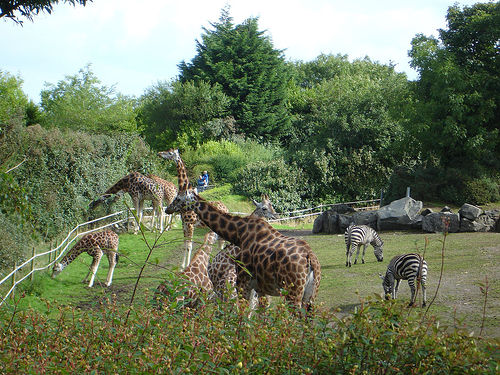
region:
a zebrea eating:
[374, 256, 449, 313]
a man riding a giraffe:
[154, 149, 287, 192]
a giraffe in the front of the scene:
[164, 184, 347, 326]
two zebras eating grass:
[339, 226, 434, 315]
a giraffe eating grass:
[49, 226, 164, 298]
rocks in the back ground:
[366, 190, 460, 215]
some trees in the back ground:
[208, 43, 447, 140]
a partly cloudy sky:
[82, 21, 204, 58]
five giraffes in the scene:
[41, 131, 416, 363]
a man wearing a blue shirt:
[199, 170, 232, 197]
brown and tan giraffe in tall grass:
[163, 186, 320, 322]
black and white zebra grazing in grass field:
[373, 253, 430, 308]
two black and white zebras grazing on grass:
[337, 224, 432, 311]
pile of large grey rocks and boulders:
[313, 196, 498, 232]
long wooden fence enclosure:
[0, 189, 385, 313]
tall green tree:
[180, 3, 299, 151]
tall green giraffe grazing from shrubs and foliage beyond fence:
[86, 163, 176, 235]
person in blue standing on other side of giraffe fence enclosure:
[193, 166, 213, 194]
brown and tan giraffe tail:
[304, 249, 321, 316]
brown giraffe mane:
[193, 188, 244, 221]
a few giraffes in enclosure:
[50, 127, 330, 337]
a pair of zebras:
[332, 215, 448, 305]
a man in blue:
[190, 165, 215, 186]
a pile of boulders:
[320, 164, 491, 246]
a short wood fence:
[3, 202, 148, 267]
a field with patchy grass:
[96, 192, 498, 336]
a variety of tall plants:
[18, 112, 350, 187]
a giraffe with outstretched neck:
[151, 141, 217, 258]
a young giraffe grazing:
[43, 221, 133, 303]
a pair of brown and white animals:
[85, 165, 178, 234]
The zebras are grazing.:
[323, 198, 457, 320]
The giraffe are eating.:
[34, 135, 327, 321]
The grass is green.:
[75, 187, 496, 332]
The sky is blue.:
[6, 7, 346, 73]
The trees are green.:
[158, 2, 496, 178]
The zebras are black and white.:
[334, 216, 436, 302]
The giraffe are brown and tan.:
[50, 132, 312, 317]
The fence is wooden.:
[0, 175, 180, 307]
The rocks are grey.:
[307, 182, 498, 242]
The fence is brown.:
[0, 192, 162, 311]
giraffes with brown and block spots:
[177, 180, 322, 291]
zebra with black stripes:
[377, 245, 433, 313]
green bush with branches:
[65, 304, 163, 361]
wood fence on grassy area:
[7, 254, 47, 292]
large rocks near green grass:
[398, 193, 496, 243]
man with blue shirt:
[192, 166, 217, 191]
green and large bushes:
[221, 142, 293, 191]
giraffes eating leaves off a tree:
[80, 151, 175, 227]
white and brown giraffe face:
[249, 183, 292, 229]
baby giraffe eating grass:
[39, 226, 131, 292]